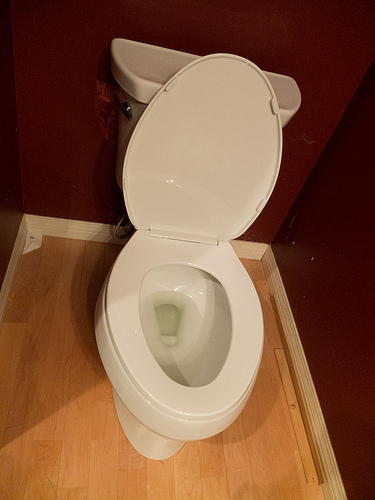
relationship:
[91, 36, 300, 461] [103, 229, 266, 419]
toilet has toilet seat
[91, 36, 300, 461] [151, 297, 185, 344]
toilet has drain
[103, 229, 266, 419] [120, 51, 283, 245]
toilet seat has cover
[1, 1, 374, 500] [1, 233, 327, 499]
bathroom has floor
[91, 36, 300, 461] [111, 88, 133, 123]
toilet has flush lever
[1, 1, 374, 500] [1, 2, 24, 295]
bathroom has right wall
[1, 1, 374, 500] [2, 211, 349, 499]
bathroom has paneling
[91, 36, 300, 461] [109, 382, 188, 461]
toilet has bottom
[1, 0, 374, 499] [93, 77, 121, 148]
wall has flaws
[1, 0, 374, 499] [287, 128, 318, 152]
wall has flaws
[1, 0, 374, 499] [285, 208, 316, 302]
wall has flaws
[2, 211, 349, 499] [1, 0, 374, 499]
paneling at bottom of wall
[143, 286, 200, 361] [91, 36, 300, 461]
water inside of toilet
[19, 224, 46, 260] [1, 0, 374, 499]
toilet paper resting in corner of wall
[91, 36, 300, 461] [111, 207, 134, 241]
toilet has hose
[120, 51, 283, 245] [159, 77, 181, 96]
cover has hinges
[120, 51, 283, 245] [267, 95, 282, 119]
cover has hinges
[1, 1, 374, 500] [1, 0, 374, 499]
bathroom has wall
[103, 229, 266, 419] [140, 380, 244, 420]
toilet seat has front end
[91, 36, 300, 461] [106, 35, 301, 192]
toilet has toilet tank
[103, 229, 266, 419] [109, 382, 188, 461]
toilet seat has bottom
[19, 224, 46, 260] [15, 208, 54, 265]
toilet paper laying in corner